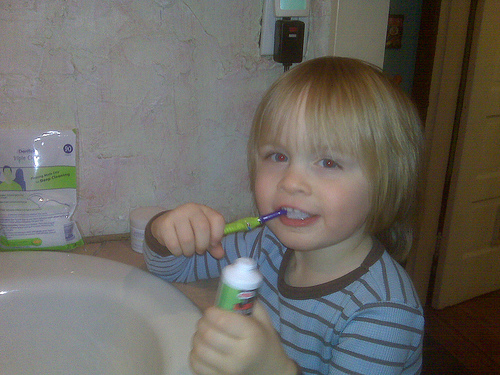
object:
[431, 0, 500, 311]
door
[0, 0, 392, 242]
wall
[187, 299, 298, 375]
hand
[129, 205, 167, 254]
vat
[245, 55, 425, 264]
hair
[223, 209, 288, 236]
toothbrush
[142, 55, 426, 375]
boy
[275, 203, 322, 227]
mouth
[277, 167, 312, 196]
nose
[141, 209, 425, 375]
shirt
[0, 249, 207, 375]
sink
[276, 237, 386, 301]
collar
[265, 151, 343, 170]
eyes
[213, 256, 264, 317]
tooth paste